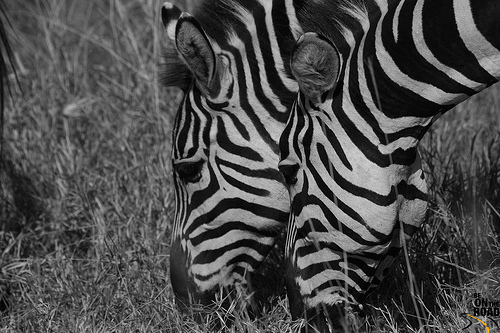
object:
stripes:
[214, 114, 265, 163]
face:
[271, 102, 392, 328]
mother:
[144, 0, 302, 326]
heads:
[148, 0, 294, 327]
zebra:
[270, 0, 499, 330]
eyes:
[168, 154, 210, 185]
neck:
[177, 0, 327, 96]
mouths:
[274, 261, 395, 333]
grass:
[429, 82, 499, 308]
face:
[166, 97, 292, 327]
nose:
[166, 233, 196, 326]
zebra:
[134, 0, 333, 330]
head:
[269, 27, 433, 330]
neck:
[339, 0, 500, 155]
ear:
[159, 0, 185, 46]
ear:
[288, 28, 342, 101]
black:
[0, 160, 94, 258]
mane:
[155, 0, 259, 101]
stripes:
[467, 0, 500, 54]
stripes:
[312, 115, 354, 173]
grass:
[0, 0, 174, 333]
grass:
[171, 305, 500, 333]